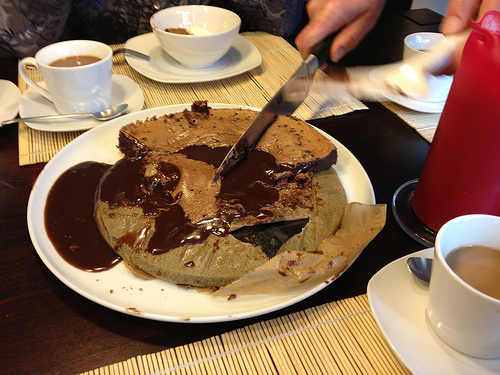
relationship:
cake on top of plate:
[93, 101, 348, 289] [26, 102, 378, 325]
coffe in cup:
[48, 55, 103, 68] [19, 39, 114, 116]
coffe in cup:
[446, 245, 500, 299] [426, 214, 500, 362]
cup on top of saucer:
[19, 39, 114, 116] [17, 73, 147, 133]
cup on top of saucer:
[426, 214, 500, 362] [366, 247, 498, 375]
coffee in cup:
[48, 55, 103, 68] [19, 39, 114, 116]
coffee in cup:
[446, 245, 500, 299] [426, 214, 500, 362]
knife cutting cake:
[212, 35, 339, 187] [93, 101, 348, 289]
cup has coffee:
[19, 39, 114, 116] [48, 55, 103, 68]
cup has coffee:
[426, 214, 500, 362] [446, 245, 500, 299]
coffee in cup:
[418, 48, 439, 53] [403, 32, 452, 100]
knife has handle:
[212, 35, 339, 187] [311, 34, 338, 67]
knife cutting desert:
[212, 35, 339, 187] [93, 101, 348, 289]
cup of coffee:
[19, 39, 114, 116] [418, 48, 439, 53]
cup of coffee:
[19, 39, 114, 116] [48, 55, 103, 68]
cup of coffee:
[426, 214, 500, 362] [446, 245, 500, 299]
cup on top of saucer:
[403, 32, 452, 100] [369, 60, 455, 114]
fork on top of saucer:
[23, 48, 150, 70] [123, 31, 264, 84]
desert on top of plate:
[93, 101, 348, 289] [26, 102, 378, 325]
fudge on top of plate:
[93, 101, 348, 289] [26, 102, 378, 325]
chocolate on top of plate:
[44, 144, 320, 273] [26, 102, 378, 325]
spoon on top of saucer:
[1, 103, 129, 125] [17, 73, 147, 133]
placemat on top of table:
[15, 27, 369, 168] [0, 7, 499, 374]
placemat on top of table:
[80, 293, 414, 374] [0, 7, 499, 374]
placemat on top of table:
[344, 62, 453, 145] [0, 7, 499, 374]